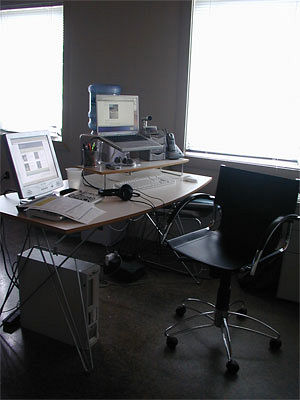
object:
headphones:
[98, 183, 141, 201]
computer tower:
[16, 246, 100, 349]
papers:
[23, 196, 106, 225]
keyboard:
[16, 188, 105, 222]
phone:
[166, 133, 183, 160]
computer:
[3, 129, 102, 221]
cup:
[65, 167, 84, 190]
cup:
[83, 150, 99, 168]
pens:
[83, 142, 97, 168]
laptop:
[96, 94, 162, 153]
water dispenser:
[87, 84, 120, 161]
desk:
[0, 157, 212, 378]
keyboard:
[112, 173, 176, 192]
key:
[132, 181, 140, 185]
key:
[143, 176, 150, 183]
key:
[145, 178, 151, 187]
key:
[141, 180, 147, 186]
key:
[146, 182, 150, 185]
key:
[151, 178, 157, 182]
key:
[168, 175, 172, 182]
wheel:
[226, 360, 239, 375]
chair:
[165, 163, 300, 375]